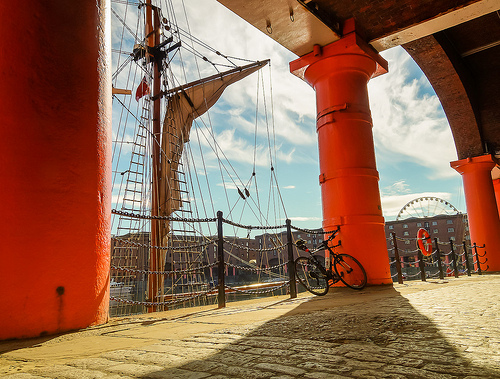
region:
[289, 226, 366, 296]
A bicycle parked by the fence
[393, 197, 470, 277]
A Ferris wheel by the water.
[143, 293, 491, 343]
Brick side walk by the water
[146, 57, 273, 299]
A sail on a ship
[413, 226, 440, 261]
Orange life raft on fence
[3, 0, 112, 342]
Orange support beams for building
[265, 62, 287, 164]
this is a string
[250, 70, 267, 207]
this is a string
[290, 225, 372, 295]
this is a bicycle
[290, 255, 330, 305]
this is a tyre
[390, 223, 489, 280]
this is a string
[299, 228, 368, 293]
THIS IS A BIKE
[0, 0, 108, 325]
THIS IS A PILLAR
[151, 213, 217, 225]
THIS IS A CHAIN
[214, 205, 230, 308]
THIS IS A POLE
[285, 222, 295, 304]
THIS IS A POLE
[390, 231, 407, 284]
THIS IS A POLE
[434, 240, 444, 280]
THIS IS A POLE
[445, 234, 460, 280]
THIS IS A POLE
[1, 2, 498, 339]
arched roof on orange columns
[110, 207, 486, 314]
hanging chains on posts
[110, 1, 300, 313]
ropes suspended from boat mast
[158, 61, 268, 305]
sail hanging from horizontal pole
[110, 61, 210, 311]
two ladders on each side of mast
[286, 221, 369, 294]
bike leaning against chain fence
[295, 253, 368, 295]
two tilted bike tires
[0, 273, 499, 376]
cobblestone surface of ground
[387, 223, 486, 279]
orange life saver on chain fence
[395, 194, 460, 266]
top of ferris wheel behind building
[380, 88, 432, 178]
white clouds in sky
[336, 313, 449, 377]
tan brick on walk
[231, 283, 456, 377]
a shadow on thew walk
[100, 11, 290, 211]
a bunch of lines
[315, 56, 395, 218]
a large orange pillar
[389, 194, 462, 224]
a friswheel in back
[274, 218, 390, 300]
a parked bike by pole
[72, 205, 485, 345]
a rope fence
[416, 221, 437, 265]
a orange life vest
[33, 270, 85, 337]
a black spot on pillar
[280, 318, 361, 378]
the shadow on the ground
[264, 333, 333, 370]
the ground is made of bricks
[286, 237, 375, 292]
a bike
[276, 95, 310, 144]
a white cloud